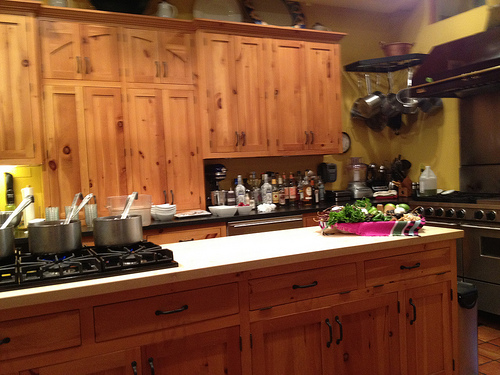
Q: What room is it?
A: It is a kitchen.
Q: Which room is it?
A: It is a kitchen.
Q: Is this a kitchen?
A: Yes, it is a kitchen.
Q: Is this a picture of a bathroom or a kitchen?
A: It is showing a kitchen.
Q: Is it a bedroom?
A: No, it is a kitchen.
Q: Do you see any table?
A: Yes, there is a table.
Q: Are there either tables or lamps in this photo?
A: Yes, there is a table.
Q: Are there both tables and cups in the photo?
A: No, there is a table but no cups.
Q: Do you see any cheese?
A: No, there is no cheese.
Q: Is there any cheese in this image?
A: No, there is no cheese.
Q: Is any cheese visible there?
A: No, there is no cheese.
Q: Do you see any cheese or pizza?
A: No, there are no cheese or pizzas.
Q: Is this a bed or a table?
A: This is a table.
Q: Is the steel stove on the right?
A: Yes, the stove is on the right of the image.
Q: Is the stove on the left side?
A: No, the stove is on the right of the image.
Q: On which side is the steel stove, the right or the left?
A: The stove is on the right of the image.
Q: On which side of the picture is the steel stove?
A: The stove is on the right of the image.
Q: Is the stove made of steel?
A: Yes, the stove is made of steel.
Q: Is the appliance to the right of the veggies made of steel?
A: Yes, the stove is made of steel.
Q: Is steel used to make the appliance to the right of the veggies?
A: Yes, the stove is made of steel.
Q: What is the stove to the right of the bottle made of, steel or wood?
A: The stove is made of steel.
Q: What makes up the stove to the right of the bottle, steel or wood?
A: The stove is made of steel.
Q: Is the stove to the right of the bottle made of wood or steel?
A: The stove is made of steel.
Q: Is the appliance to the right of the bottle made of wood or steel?
A: The stove is made of steel.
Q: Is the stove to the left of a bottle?
A: No, the stove is to the right of a bottle.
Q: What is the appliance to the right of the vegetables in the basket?
A: The appliance is a stove.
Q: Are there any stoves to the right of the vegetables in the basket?
A: Yes, there is a stove to the right of the vegetables.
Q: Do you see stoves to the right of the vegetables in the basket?
A: Yes, there is a stove to the right of the vegetables.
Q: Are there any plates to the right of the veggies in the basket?
A: No, there is a stove to the right of the vegetables.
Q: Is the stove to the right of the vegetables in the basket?
A: Yes, the stove is to the right of the vegetables.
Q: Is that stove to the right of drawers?
A: No, the stove is to the right of the vegetables.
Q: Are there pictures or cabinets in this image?
A: Yes, there is a cabinet.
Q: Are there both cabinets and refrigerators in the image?
A: No, there is a cabinet but no refrigerators.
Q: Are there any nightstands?
A: No, there are no nightstands.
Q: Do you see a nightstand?
A: No, there are no nightstands.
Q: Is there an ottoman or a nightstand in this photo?
A: No, there are no nightstands or ottomen.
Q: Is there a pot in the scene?
A: Yes, there is a pot.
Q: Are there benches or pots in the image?
A: Yes, there is a pot.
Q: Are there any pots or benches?
A: Yes, there is a pot.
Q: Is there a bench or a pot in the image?
A: Yes, there is a pot.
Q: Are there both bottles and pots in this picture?
A: Yes, there are both a pot and a bottle.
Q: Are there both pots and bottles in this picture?
A: Yes, there are both a pot and a bottle.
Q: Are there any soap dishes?
A: No, there are no soap dishes.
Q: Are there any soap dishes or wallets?
A: No, there are no soap dishes or wallets.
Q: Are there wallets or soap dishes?
A: No, there are no soap dishes or wallets.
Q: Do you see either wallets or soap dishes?
A: No, there are no soap dishes or wallets.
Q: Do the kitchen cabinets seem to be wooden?
A: Yes, the cabinets are wooden.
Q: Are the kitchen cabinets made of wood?
A: Yes, the cabinets are made of wood.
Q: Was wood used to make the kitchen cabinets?
A: Yes, the cabinets are made of wood.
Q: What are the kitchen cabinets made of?
A: The cabinets are made of wood.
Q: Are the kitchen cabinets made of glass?
A: No, the cabinets are made of wood.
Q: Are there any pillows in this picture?
A: No, there are no pillows.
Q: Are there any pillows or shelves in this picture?
A: No, there are no pillows or shelves.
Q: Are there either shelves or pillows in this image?
A: No, there are no pillows or shelves.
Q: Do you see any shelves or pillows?
A: No, there are no pillows or shelves.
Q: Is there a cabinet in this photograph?
A: Yes, there is a cabinet.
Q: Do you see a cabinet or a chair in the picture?
A: Yes, there is a cabinet.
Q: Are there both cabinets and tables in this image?
A: Yes, there are both a cabinet and a table.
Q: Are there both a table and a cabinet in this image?
A: Yes, there are both a cabinet and a table.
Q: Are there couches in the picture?
A: No, there are no couches.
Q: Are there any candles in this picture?
A: No, there are no candles.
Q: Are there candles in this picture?
A: No, there are no candles.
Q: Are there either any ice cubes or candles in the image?
A: No, there are no candles or ice cubes.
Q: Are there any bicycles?
A: No, there are no bicycles.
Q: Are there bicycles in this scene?
A: No, there are no bicycles.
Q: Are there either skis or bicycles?
A: No, there are no bicycles or skis.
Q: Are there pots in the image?
A: Yes, there is a pot.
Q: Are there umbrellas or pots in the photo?
A: Yes, there is a pot.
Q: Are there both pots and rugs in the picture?
A: No, there is a pot but no rugs.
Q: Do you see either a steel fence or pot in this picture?
A: Yes, there is a steel pot.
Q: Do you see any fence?
A: No, there are no fences.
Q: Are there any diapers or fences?
A: No, there are no fences or diapers.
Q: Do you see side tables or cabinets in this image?
A: Yes, there is a cabinet.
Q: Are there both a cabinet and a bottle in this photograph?
A: Yes, there are both a cabinet and a bottle.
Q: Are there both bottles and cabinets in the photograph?
A: Yes, there are both a cabinet and a bottle.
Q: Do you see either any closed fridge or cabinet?
A: Yes, there is a closed cabinet.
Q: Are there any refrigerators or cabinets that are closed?
A: Yes, the cabinet is closed.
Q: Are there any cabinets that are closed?
A: Yes, there is a closed cabinet.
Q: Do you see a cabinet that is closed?
A: Yes, there is a cabinet that is closed.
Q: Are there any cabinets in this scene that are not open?
A: Yes, there is an closed cabinet.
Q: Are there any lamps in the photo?
A: No, there are no lamps.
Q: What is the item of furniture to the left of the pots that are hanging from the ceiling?
A: The piece of furniture is a cabinet.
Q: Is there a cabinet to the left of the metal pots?
A: Yes, there is a cabinet to the left of the pots.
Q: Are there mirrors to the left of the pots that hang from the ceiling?
A: No, there is a cabinet to the left of the pots.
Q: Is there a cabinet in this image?
A: Yes, there is a cabinet.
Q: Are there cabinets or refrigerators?
A: Yes, there is a cabinet.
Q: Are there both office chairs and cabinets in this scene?
A: No, there is a cabinet but no office chairs.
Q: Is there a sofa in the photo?
A: No, there are no sofas.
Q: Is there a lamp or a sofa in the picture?
A: No, there are no sofas or lamps.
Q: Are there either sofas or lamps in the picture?
A: No, there are no sofas or lamps.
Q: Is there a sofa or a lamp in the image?
A: No, there are no sofas or lamps.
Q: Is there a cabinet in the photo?
A: Yes, there is a cabinet.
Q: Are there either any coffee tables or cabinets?
A: Yes, there is a cabinet.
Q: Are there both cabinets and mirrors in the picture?
A: No, there is a cabinet but no mirrors.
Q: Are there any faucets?
A: No, there are no faucets.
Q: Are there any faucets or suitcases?
A: No, there are no faucets or suitcases.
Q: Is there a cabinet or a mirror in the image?
A: Yes, there is a cabinet.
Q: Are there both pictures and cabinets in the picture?
A: No, there is a cabinet but no pictures.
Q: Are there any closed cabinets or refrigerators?
A: Yes, there is a closed cabinet.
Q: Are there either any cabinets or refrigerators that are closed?
A: Yes, the cabinet is closed.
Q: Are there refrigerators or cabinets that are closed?
A: Yes, the cabinet is closed.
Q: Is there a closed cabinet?
A: Yes, there is a closed cabinet.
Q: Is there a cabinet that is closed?
A: Yes, there is a cabinet that is closed.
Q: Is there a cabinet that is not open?
A: Yes, there is an closed cabinet.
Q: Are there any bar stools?
A: No, there are no bar stools.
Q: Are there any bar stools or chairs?
A: No, there are no bar stools or chairs.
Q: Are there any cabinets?
A: Yes, there is a cabinet.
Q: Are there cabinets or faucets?
A: Yes, there is a cabinet.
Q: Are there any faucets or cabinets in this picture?
A: Yes, there is a cabinet.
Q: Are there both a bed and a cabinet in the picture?
A: No, there is a cabinet but no beds.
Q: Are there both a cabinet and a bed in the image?
A: No, there is a cabinet but no beds.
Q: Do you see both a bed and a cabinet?
A: No, there is a cabinet but no beds.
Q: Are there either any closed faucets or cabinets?
A: Yes, there is a closed cabinet.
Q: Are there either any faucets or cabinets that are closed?
A: Yes, the cabinet is closed.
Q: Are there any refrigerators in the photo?
A: No, there are no refrigerators.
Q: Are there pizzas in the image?
A: No, there are no pizzas.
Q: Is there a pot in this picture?
A: Yes, there is a pot.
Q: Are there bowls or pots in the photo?
A: Yes, there is a pot.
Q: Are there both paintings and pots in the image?
A: No, there is a pot but no paintings.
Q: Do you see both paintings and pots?
A: No, there is a pot but no paintings.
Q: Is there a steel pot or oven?
A: Yes, there is a steel pot.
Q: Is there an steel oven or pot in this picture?
A: Yes, there is a steel pot.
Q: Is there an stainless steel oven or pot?
A: Yes, there is a stainless steel pot.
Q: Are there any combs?
A: No, there are no combs.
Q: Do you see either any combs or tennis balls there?
A: No, there are no combs or tennis balls.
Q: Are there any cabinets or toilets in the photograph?
A: Yes, there is a cabinet.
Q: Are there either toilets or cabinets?
A: Yes, there is a cabinet.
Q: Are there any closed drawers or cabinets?
A: Yes, there is a closed cabinet.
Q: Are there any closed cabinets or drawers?
A: Yes, there is a closed cabinet.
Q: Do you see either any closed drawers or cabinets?
A: Yes, there is a closed cabinet.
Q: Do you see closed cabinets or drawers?
A: Yes, there is a closed cabinet.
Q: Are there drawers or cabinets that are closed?
A: Yes, the cabinet is closed.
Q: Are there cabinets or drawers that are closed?
A: Yes, the cabinet is closed.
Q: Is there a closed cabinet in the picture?
A: Yes, there is a closed cabinet.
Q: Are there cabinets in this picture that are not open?
A: Yes, there is an closed cabinet.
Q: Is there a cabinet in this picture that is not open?
A: Yes, there is an closed cabinet.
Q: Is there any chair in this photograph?
A: No, there are no chairs.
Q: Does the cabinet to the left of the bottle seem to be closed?
A: Yes, the cabinet is closed.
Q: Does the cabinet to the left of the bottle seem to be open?
A: No, the cabinet is closed.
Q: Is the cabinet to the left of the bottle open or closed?
A: The cabinet is closed.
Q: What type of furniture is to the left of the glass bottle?
A: The piece of furniture is a cabinet.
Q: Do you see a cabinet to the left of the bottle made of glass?
A: Yes, there is a cabinet to the left of the bottle.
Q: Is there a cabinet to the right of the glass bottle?
A: No, the cabinet is to the left of the bottle.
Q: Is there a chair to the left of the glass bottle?
A: No, there is a cabinet to the left of the bottle.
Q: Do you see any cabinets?
A: Yes, there is a cabinet.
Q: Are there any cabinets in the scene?
A: Yes, there is a cabinet.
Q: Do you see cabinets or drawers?
A: Yes, there is a cabinet.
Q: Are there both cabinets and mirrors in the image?
A: No, there is a cabinet but no mirrors.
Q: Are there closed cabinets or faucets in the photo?
A: Yes, there is a closed cabinet.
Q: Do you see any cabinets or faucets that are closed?
A: Yes, the cabinet is closed.